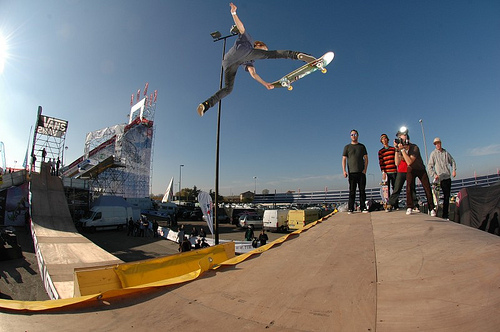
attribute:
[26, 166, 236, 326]
ramp — wooden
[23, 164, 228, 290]
skateboarding rink — wooden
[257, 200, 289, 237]
van — white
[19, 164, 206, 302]
ramp — wooden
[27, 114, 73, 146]
sign — white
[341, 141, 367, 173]
shirt — black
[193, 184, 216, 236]
flag — oval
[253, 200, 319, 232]
vans — transport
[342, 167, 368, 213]
pants — black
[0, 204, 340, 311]
tarp — yellow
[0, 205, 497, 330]
skateboard landing — wooden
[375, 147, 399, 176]
shirt — red, black, striped